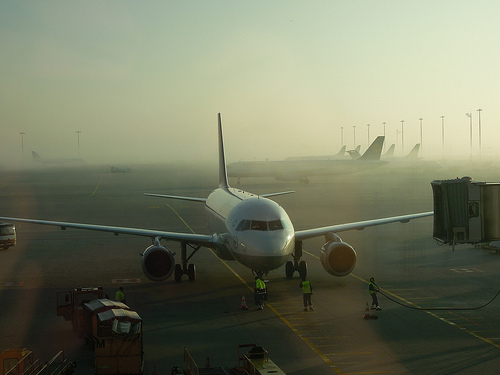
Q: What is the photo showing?
A: It is showing a runway.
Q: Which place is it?
A: It is a runway.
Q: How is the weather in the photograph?
A: It is cloudy.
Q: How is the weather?
A: It is cloudy.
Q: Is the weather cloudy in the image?
A: Yes, it is cloudy.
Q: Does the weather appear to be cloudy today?
A: Yes, it is cloudy.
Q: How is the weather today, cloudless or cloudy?
A: It is cloudy.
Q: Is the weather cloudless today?
A: No, it is cloudy.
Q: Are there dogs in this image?
A: No, there are no dogs.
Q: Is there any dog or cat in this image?
A: No, there are no dogs or cats.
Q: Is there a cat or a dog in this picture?
A: No, there are no dogs or cats.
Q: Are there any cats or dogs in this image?
A: No, there are no dogs or cats.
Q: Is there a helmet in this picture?
A: No, there are no helmets.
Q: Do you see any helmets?
A: No, there are no helmets.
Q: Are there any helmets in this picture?
A: No, there are no helmets.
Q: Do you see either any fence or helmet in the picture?
A: No, there are no helmets or fences.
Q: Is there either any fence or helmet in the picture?
A: No, there are no helmets or fences.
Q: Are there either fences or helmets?
A: No, there are no helmets or fences.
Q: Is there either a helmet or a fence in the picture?
A: No, there are no helmets or fences.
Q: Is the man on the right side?
A: Yes, the man is on the right of the image.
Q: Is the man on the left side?
A: No, the man is on the right of the image.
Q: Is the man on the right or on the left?
A: The man is on the right of the image.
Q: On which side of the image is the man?
A: The man is on the right of the image.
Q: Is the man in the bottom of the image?
A: Yes, the man is in the bottom of the image.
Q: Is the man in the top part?
A: No, the man is in the bottom of the image.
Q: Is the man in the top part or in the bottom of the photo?
A: The man is in the bottom of the image.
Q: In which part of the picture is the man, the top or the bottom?
A: The man is in the bottom of the image.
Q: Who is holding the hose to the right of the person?
A: The man is holding the water hose.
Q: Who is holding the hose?
A: The man is holding the water hose.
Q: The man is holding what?
A: The man is holding the water hose.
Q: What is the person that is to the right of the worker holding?
A: The man is holding the water hose.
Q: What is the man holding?
A: The man is holding the water hose.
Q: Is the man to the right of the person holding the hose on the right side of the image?
A: Yes, the man is holding the water hose.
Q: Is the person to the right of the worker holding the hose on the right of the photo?
A: Yes, the man is holding the water hose.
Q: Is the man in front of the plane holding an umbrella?
A: No, the man is holding the water hose.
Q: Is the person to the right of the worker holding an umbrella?
A: No, the man is holding the water hose.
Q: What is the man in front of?
A: The man is in front of the plane.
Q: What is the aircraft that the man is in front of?
A: The aircraft is an airplane.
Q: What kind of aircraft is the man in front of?
A: The man is in front of the airplane.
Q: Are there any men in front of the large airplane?
A: Yes, there is a man in front of the airplane.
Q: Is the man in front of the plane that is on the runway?
A: Yes, the man is in front of the airplane.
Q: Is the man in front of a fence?
A: No, the man is in front of the airplane.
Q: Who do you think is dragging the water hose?
A: The man is dragging the water hose.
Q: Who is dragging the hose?
A: The man is dragging the water hose.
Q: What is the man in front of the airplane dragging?
A: The man is dragging the hose.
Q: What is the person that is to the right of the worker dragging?
A: The man is dragging the hose.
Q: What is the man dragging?
A: The man is dragging the hose.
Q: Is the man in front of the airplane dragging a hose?
A: Yes, the man is dragging a hose.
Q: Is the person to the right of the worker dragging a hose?
A: Yes, the man is dragging a hose.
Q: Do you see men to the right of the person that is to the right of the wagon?
A: Yes, there is a man to the right of the person.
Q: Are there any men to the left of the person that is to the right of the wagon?
A: No, the man is to the right of the person.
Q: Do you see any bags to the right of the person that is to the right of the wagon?
A: No, there is a man to the right of the person.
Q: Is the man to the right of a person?
A: Yes, the man is to the right of a person.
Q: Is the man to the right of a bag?
A: No, the man is to the right of a person.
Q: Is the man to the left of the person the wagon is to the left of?
A: No, the man is to the right of the person.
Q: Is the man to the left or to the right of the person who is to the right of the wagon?
A: The man is to the right of the person.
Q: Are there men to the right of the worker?
A: Yes, there is a man to the right of the worker.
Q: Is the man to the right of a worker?
A: Yes, the man is to the right of a worker.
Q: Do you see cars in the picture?
A: No, there are no cars.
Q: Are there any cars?
A: No, there are no cars.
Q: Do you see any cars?
A: No, there are no cars.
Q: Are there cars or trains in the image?
A: No, there are no cars or trains.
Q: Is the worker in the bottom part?
A: Yes, the worker is in the bottom of the image.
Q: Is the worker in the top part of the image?
A: No, the worker is in the bottom of the image.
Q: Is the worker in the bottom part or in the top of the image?
A: The worker is in the bottom of the image.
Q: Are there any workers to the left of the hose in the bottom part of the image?
A: Yes, there is a worker to the left of the hose.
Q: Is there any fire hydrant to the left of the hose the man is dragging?
A: No, there is a worker to the left of the water hose.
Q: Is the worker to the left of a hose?
A: Yes, the worker is to the left of a hose.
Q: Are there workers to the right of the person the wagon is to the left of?
A: Yes, there is a worker to the right of the person.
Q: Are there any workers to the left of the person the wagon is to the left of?
A: No, the worker is to the right of the person.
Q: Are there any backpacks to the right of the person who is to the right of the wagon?
A: No, there is a worker to the right of the person.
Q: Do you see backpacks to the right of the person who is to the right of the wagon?
A: No, there is a worker to the right of the person.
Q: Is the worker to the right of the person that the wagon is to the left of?
A: Yes, the worker is to the right of the person.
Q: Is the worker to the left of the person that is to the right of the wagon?
A: No, the worker is to the right of the person.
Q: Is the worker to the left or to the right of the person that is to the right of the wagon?
A: The worker is to the right of the person.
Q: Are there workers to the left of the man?
A: Yes, there is a worker to the left of the man.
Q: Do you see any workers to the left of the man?
A: Yes, there is a worker to the left of the man.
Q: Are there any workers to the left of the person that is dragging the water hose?
A: Yes, there is a worker to the left of the man.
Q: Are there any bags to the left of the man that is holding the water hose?
A: No, there is a worker to the left of the man.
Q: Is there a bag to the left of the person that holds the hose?
A: No, there is a worker to the left of the man.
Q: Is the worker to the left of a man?
A: Yes, the worker is to the left of a man.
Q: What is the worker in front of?
A: The worker is in front of the plane.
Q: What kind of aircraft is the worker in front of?
A: The worker is in front of the airplane.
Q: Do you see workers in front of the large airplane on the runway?
A: Yes, there is a worker in front of the plane.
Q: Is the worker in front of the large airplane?
A: Yes, the worker is in front of the airplane.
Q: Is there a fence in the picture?
A: No, there are no fences.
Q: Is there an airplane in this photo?
A: Yes, there is an airplane.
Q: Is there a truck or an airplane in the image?
A: Yes, there is an airplane.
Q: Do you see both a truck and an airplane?
A: Yes, there are both an airplane and a truck.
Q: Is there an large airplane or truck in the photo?
A: Yes, there is a large airplane.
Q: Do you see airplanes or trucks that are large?
A: Yes, the airplane is large.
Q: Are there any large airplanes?
A: Yes, there is a large airplane.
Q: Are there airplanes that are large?
A: Yes, there is an airplane that is large.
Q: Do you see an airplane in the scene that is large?
A: Yes, there is an airplane that is large.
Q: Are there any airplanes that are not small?
A: Yes, there is a large airplane.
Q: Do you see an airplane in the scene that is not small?
A: Yes, there is a large airplane.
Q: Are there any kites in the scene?
A: No, there are no kites.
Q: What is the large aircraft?
A: The aircraft is an airplane.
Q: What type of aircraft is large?
A: The aircraft is an airplane.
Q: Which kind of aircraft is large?
A: The aircraft is an airplane.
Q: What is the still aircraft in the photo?
A: The aircraft is an airplane.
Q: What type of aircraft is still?
A: The aircraft is an airplane.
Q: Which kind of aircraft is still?
A: The aircraft is an airplane.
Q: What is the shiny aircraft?
A: The aircraft is an airplane.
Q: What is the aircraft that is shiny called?
A: The aircraft is an airplane.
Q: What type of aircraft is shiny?
A: The aircraft is an airplane.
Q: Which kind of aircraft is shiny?
A: The aircraft is an airplane.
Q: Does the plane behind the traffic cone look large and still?
A: Yes, the plane is large and still.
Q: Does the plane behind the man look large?
A: Yes, the plane is large.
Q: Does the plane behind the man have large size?
A: Yes, the plane is large.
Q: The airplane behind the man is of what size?
A: The plane is large.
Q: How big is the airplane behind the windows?
A: The plane is large.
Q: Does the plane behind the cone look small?
A: No, the plane is large.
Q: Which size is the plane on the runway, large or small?
A: The airplane is large.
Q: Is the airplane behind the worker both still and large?
A: Yes, the airplane is still and large.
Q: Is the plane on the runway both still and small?
A: No, the airplane is still but large.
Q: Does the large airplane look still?
A: Yes, the airplane is still.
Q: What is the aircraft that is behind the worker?
A: The aircraft is an airplane.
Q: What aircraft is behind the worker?
A: The aircraft is an airplane.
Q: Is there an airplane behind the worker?
A: Yes, there is an airplane behind the worker.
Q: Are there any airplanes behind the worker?
A: Yes, there is an airplane behind the worker.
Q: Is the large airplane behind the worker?
A: Yes, the plane is behind the worker.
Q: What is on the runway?
A: The plane is on the runway.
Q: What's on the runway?
A: The plane is on the runway.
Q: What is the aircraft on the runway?
A: The aircraft is an airplane.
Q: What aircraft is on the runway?
A: The aircraft is an airplane.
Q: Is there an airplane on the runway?
A: Yes, there is an airplane on the runway.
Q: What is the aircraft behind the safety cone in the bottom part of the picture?
A: The aircraft is an airplane.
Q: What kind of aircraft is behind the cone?
A: The aircraft is an airplane.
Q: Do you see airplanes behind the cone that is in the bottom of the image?
A: Yes, there is an airplane behind the cone.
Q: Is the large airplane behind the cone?
A: Yes, the airplane is behind the cone.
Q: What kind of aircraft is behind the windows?
A: The aircraft is an airplane.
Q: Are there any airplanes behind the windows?
A: Yes, there is an airplane behind the windows.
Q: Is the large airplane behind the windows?
A: Yes, the airplane is behind the windows.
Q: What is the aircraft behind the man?
A: The aircraft is an airplane.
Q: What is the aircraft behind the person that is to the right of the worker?
A: The aircraft is an airplane.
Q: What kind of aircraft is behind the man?
A: The aircraft is an airplane.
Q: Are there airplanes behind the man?
A: Yes, there is an airplane behind the man.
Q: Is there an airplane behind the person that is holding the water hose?
A: Yes, there is an airplane behind the man.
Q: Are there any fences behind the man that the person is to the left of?
A: No, there is an airplane behind the man.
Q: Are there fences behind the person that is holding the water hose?
A: No, there is an airplane behind the man.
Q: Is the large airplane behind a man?
A: Yes, the airplane is behind a man.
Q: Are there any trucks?
A: Yes, there is a truck.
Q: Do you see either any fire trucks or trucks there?
A: Yes, there is a truck.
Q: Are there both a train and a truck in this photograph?
A: No, there is a truck but no trains.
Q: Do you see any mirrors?
A: No, there are no mirrors.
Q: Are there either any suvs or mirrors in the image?
A: No, there are no mirrors or suvs.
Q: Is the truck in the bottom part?
A: Yes, the truck is in the bottom of the image.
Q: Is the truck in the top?
A: No, the truck is in the bottom of the image.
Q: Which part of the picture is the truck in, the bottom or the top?
A: The truck is in the bottom of the image.